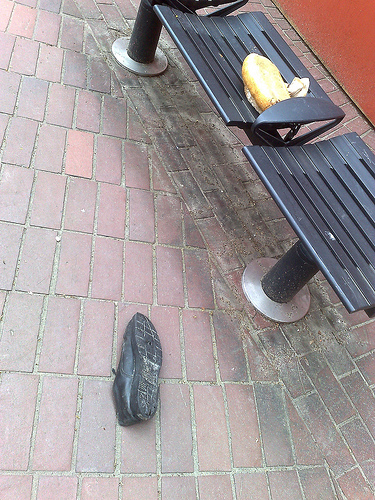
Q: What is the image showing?
A: It is showing a sidewalk.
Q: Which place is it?
A: It is a sidewalk.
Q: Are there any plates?
A: Yes, there is a plate.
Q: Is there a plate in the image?
A: Yes, there is a plate.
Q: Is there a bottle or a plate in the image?
A: Yes, there is a plate.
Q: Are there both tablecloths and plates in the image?
A: No, there is a plate but no tablecloths.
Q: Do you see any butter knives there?
A: No, there are no butter knives.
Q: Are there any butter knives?
A: No, there are no butter knives.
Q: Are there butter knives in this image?
A: No, there are no butter knives.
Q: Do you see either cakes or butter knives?
A: No, there are no butter knives or cakes.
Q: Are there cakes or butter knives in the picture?
A: No, there are no butter knives or cakes.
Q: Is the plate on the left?
A: No, the plate is on the right of the image.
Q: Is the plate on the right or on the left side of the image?
A: The plate is on the right of the image.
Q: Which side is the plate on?
A: The plate is on the right of the image.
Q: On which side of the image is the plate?
A: The plate is on the right of the image.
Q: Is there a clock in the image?
A: No, there are no clocks.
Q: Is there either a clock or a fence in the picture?
A: No, there are no clocks or fences.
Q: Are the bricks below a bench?
A: Yes, the bricks are below a bench.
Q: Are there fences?
A: No, there are no fences.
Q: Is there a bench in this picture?
A: Yes, there is a bench.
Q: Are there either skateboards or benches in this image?
A: Yes, there is a bench.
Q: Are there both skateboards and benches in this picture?
A: No, there is a bench but no skateboards.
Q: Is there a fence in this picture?
A: No, there are no fences.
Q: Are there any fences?
A: No, there are no fences.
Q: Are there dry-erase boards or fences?
A: No, there are no fences or dry-erase boards.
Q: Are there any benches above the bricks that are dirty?
A: Yes, there is a bench above the bricks.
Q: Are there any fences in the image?
A: No, there are no fences.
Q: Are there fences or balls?
A: No, there are no fences or balls.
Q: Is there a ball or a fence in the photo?
A: No, there are no fences or balls.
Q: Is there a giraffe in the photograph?
A: No, there are no giraffes.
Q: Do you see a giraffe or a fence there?
A: No, there are no giraffes or fences.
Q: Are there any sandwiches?
A: Yes, there is a sandwich.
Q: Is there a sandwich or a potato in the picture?
A: Yes, there is a sandwich.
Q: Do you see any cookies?
A: No, there are no cookies.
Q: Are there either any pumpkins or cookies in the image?
A: No, there are no cookies or pumpkins.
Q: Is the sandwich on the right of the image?
A: Yes, the sandwich is on the right of the image.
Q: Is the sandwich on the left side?
A: No, the sandwich is on the right of the image.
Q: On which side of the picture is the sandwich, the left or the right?
A: The sandwich is on the right of the image.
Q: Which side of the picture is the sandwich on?
A: The sandwich is on the right of the image.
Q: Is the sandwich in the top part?
A: Yes, the sandwich is in the top of the image.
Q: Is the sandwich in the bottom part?
A: No, the sandwich is in the top of the image.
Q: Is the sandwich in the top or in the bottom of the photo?
A: The sandwich is in the top of the image.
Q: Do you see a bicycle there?
A: No, there are no bicycles.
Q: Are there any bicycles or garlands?
A: No, there are no bicycles or garlands.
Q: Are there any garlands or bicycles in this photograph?
A: No, there are no bicycles or garlands.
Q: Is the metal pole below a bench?
A: Yes, the pole is below a bench.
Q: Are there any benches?
A: Yes, there is a bench.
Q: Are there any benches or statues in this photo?
A: Yes, there is a bench.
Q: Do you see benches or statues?
A: Yes, there is a bench.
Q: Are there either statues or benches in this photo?
A: Yes, there is a bench.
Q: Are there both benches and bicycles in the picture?
A: No, there is a bench but no bicycles.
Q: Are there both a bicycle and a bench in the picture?
A: No, there is a bench but no bicycles.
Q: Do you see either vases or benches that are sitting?
A: Yes, the bench is sitting.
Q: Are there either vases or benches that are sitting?
A: Yes, the bench is sitting.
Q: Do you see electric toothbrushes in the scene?
A: No, there are no electric toothbrushes.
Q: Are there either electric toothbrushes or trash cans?
A: No, there are no electric toothbrushes or trash cans.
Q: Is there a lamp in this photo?
A: No, there are no lamps.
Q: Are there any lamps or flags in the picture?
A: No, there are no lamps or flags.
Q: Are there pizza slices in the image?
A: No, there are no pizza slices.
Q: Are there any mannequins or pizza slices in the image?
A: No, there are no pizza slices or mannequins.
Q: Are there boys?
A: No, there are no boys.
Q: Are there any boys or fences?
A: No, there are no boys or fences.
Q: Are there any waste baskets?
A: No, there are no waste baskets.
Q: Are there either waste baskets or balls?
A: No, there are no waste baskets or balls.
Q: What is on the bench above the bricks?
A: The trash is on the bench.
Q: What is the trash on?
A: The trash is on the bench.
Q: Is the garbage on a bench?
A: Yes, the garbage is on a bench.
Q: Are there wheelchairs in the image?
A: No, there are no wheelchairs.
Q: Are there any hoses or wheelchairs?
A: No, there are no wheelchairs or hoses.